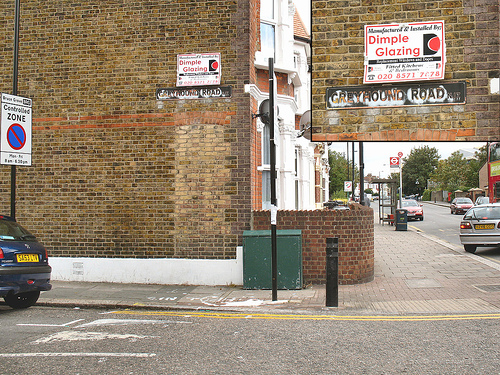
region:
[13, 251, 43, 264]
A yellow and black license plate.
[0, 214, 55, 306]
A blue hatchback sedan.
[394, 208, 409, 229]
A green trashcan.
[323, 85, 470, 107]
A worn sign reading "Greyhound Road"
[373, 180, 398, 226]
A bus stop.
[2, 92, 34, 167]
A street sign.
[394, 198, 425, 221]
A red parked car.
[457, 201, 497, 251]
A silver car pulling out of an entrance.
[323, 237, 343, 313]
A black pole sticking out from the sidewalk.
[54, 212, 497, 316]
The sidewalk.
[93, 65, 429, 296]
picture taken outdoors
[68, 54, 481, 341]
picture taken during the day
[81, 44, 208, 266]
the building is made of brick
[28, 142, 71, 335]
a car is parked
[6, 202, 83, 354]
the car is blue in color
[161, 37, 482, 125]
signs are on the building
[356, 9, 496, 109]
the sign says dimple glazing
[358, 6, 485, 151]
the sign is red white and black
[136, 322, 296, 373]
the street is grey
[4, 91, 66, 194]
a sign is blue and red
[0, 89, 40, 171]
The white sign with the blue circle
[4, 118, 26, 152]
The blue circle with the red line through it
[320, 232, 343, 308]
The short black post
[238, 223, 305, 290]
The green box next to wall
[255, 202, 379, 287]
The short brick wall in front of the building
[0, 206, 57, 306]
The blue car under the white sign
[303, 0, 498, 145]
The cutout of the zoomed in wall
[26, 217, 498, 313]
Sidewalk on the side and front of the building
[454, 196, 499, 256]
The silver car pulling away from the curb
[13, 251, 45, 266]
The yellow license plate on the blue car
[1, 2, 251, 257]
a large brown brick wall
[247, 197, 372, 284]
a short brown brick wall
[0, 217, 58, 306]
a parked blue car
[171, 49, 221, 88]
a business promotional sign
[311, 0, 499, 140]
a magnification of business sign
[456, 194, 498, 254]
a parked silver car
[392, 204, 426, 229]
a parked red car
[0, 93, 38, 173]
a parking information sign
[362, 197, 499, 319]
a brick paved sidewalk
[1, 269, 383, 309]
a brick paved sidewalk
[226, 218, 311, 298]
The box is green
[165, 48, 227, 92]
White sign on wall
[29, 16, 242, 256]
The building is brick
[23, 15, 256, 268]
The brick is brown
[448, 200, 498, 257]
The car is white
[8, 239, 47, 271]
Black and yellow license plate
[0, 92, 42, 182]
Sign on a black pole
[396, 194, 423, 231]
The red car is parked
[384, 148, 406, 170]
Red and white sign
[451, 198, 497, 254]
The cars lights are on